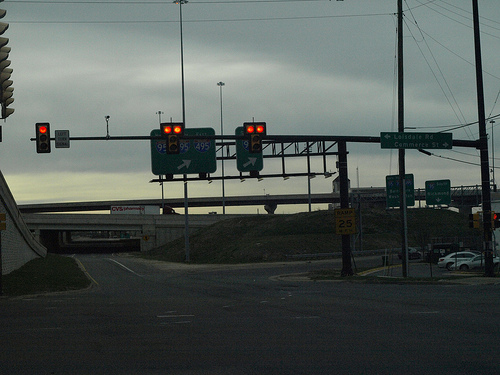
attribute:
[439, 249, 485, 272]
car — white, parked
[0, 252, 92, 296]
grass — green, patchy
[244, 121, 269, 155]
red traffic light — indicating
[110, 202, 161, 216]
trailer — white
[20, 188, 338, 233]
overpass — flyover